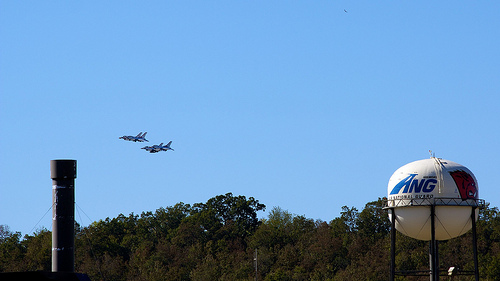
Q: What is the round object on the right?
A: Water tower.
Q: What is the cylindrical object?
A: A chimney.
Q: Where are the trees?
A: In the background.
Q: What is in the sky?
A: Airplanes.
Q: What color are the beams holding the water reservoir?
A: Black.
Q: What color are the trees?
A: Green.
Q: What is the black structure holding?
A: A glove.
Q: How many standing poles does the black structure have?
A: Four.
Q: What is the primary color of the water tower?
A: White.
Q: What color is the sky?
A: Blue.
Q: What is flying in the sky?
A: Planes.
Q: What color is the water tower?
A: White.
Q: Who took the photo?
A: Photographer.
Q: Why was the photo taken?
A: Landscape.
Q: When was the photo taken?
A: Afternoon.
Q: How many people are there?
A: Zero.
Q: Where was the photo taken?
A: On the ground.